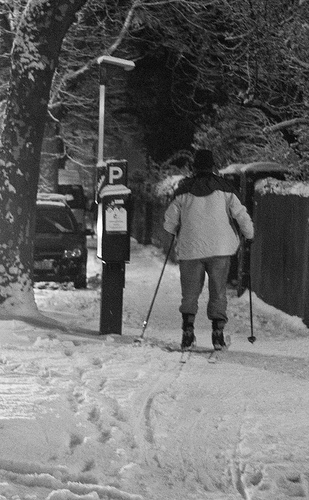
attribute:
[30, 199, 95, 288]
car —  black parked 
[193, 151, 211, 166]
hat — Black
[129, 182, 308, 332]
fence — large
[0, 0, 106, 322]
tree trnk — Large snowy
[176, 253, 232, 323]
pants — gray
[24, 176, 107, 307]
car — parked 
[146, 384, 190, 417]
snow — white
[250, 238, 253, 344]
pole — ski , black, right side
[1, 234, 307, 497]
ground — white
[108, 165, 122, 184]
letter — white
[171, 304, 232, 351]
boots — black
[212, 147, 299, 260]
fence — Dark  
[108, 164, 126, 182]
p. — Large, white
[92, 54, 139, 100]
light — street 